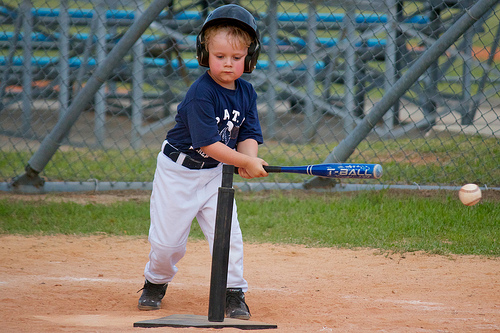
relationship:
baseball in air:
[457, 183, 483, 207] [1, 2, 499, 330]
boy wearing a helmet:
[136, 6, 263, 323] [196, 3, 260, 75]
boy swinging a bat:
[136, 6, 263, 323] [235, 160, 386, 183]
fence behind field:
[1, 2, 499, 195] [5, 138, 498, 331]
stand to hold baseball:
[132, 165, 274, 331] [457, 183, 483, 207]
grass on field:
[2, 135, 500, 261] [5, 138, 498, 331]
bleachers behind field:
[1, 7, 442, 74] [5, 138, 498, 331]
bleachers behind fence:
[1, 7, 442, 74] [1, 2, 499, 195]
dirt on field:
[2, 237, 499, 331] [5, 138, 498, 331]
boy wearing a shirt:
[136, 6, 263, 323] [166, 71, 264, 167]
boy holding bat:
[136, 6, 263, 323] [235, 160, 386, 183]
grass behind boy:
[2, 135, 500, 261] [136, 6, 263, 323]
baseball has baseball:
[457, 183, 483, 207] [459, 184, 481, 206]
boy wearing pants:
[136, 6, 263, 323] [147, 139, 250, 292]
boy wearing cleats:
[136, 6, 263, 323] [137, 275, 249, 320]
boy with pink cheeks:
[136, 6, 263, 323] [211, 58, 246, 77]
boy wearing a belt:
[136, 6, 263, 323] [162, 140, 226, 171]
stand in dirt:
[132, 165, 274, 331] [2, 237, 499, 331]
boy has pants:
[136, 6, 263, 323] [147, 139, 250, 292]